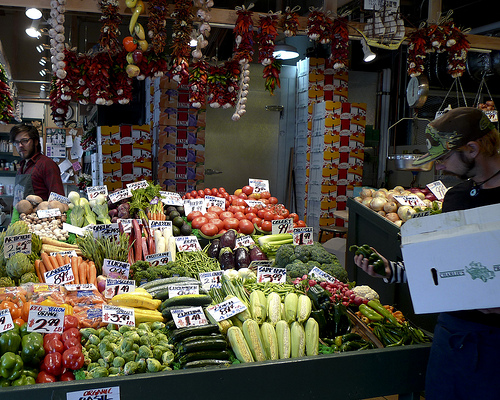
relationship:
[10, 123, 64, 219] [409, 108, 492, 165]
man has a hat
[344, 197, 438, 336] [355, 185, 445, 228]
box has produce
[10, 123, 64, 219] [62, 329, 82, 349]
man picking a peppers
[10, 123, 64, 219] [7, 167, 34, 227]
man has on an apron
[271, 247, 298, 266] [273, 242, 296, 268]
brocolee has a brocolee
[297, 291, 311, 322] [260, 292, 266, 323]
corn on a ear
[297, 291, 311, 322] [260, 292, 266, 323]
corn has a ear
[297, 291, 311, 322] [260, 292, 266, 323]
corn has an ear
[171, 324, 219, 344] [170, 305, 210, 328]
cucumbers have a sign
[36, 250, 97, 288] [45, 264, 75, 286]
carrots have a sign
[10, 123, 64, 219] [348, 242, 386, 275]
man holding peppers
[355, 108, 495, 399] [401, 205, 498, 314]
man has a box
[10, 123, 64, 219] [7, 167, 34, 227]
man has an apron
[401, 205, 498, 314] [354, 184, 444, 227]
box has vegetables